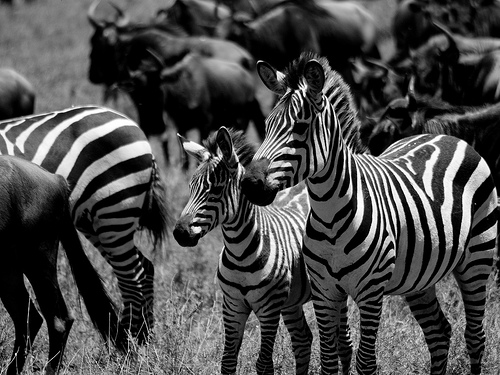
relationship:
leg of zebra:
[28, 245, 77, 374] [239, 70, 499, 364]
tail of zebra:
[58, 194, 130, 351] [0, 110, 166, 340]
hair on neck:
[283, 49, 365, 155] [305, 144, 362, 229]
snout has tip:
[171, 222, 199, 247] [173, 225, 186, 238]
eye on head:
[286, 110, 317, 141] [233, 33, 369, 219]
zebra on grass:
[239, 70, 499, 364] [3, 209, 489, 374]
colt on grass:
[172, 125, 352, 375] [3, 209, 489, 374]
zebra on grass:
[239, 50, 498, 375] [0, 0, 497, 372]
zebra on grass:
[0, 110, 166, 340] [0, 0, 497, 372]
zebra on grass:
[239, 70, 499, 364] [0, 0, 497, 372]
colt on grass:
[172, 125, 352, 375] [0, 0, 497, 372]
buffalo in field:
[115, 53, 267, 171] [2, 1, 496, 371]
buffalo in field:
[366, 89, 488, 156] [2, 1, 496, 371]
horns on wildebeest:
[88, 0, 105, 33] [84, 0, 254, 142]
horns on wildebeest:
[109, 0, 134, 27] [84, 0, 254, 142]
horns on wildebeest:
[207, 0, 226, 20] [226, 3, 356, 76]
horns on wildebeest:
[242, 3, 259, 24] [226, 3, 356, 76]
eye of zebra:
[290, 120, 308, 135] [238, 52, 495, 373]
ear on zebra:
[305, 63, 322, 98] [238, 52, 495, 373]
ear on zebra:
[256, 60, 286, 88] [238, 52, 495, 373]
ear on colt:
[217, 125, 241, 165] [172, 125, 352, 375]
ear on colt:
[178, 137, 209, 157] [172, 125, 352, 375]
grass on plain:
[0, 0, 497, 372] [3, 0, 498, 371]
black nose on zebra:
[255, 146, 272, 198] [238, 52, 495, 373]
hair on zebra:
[279, 47, 370, 158] [254, 54, 375, 363]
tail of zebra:
[137, 160, 176, 260] [2, 107, 167, 261]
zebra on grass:
[239, 50, 498, 375] [44, 288, 220, 368]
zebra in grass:
[239, 50, 498, 375] [151, 251, 203, 309]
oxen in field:
[103, 14, 447, 96] [2, 1, 496, 371]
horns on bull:
[82, 0, 135, 30] [80, 2, 270, 141]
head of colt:
[240, 52, 355, 206] [172, 125, 352, 375]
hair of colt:
[279, 47, 370, 158] [172, 125, 352, 375]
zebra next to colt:
[239, 50, 498, 375] [170, 128, 352, 370]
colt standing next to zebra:
[172, 125, 352, 375] [271, 81, 470, 306]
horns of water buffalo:
[84, 0, 131, 30] [81, 1, 264, 145]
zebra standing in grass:
[239, 50, 498, 375] [0, 0, 497, 372]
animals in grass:
[3, 1, 498, 372] [0, 0, 497, 372]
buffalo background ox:
[118, 52, 289, 147] [68, 17, 138, 95]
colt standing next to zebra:
[172, 125, 352, 375] [239, 70, 499, 364]